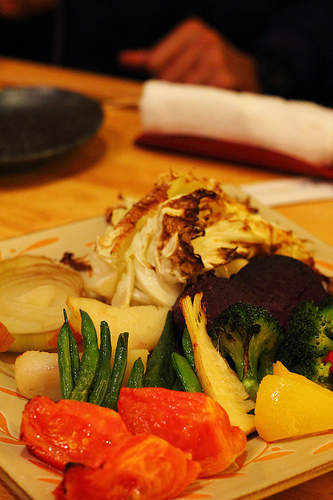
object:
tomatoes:
[91, 406, 196, 482]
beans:
[53, 312, 75, 402]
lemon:
[250, 345, 332, 446]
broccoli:
[214, 295, 290, 398]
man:
[0, 0, 309, 101]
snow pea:
[67, 305, 100, 405]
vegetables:
[117, 375, 256, 479]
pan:
[0, 76, 105, 180]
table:
[0, 59, 332, 499]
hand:
[121, 15, 258, 97]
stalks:
[228, 345, 264, 398]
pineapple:
[95, 294, 179, 358]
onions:
[0, 248, 95, 357]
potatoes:
[65, 282, 184, 358]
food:
[16, 383, 137, 471]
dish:
[0, 177, 332, 499]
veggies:
[59, 164, 333, 309]